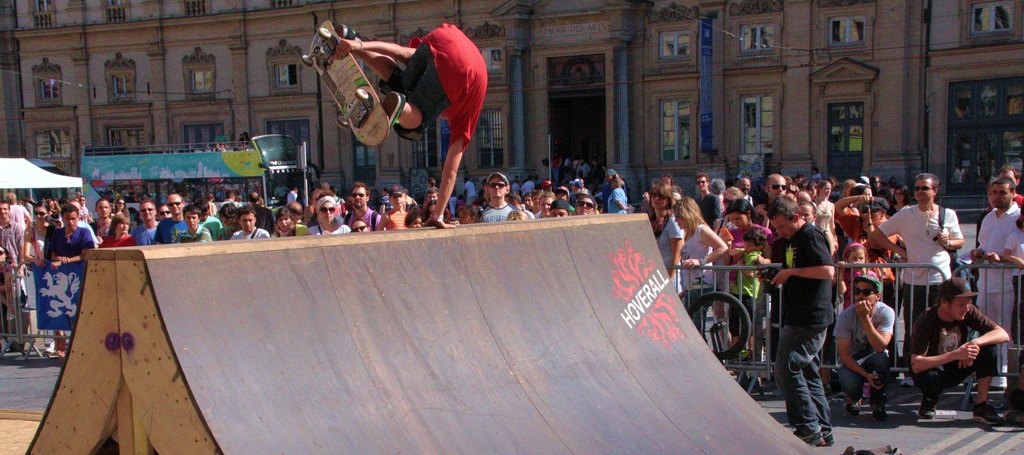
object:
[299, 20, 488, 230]
person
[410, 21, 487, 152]
shirt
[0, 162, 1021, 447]
crowd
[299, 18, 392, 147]
skateboard